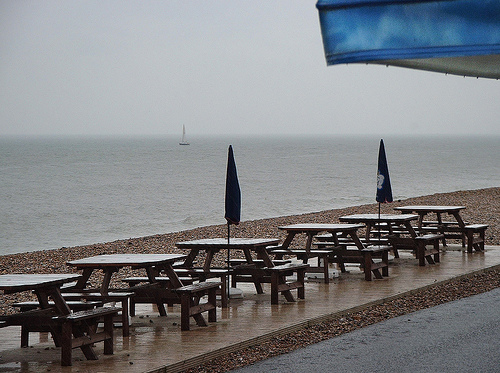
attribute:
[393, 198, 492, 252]
picnic table — wooden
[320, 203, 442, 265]
picnic table — wooden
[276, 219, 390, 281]
picnic table — wooden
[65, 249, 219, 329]
picnic table — wooden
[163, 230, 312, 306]
picnic table — wooden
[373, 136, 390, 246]
umbrella — blue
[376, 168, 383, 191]
logo — white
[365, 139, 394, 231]
canopy — blue, white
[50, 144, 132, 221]
water — large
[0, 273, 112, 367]
table — wooden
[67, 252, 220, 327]
table — wooden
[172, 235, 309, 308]
table — wooden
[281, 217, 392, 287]
table — wooden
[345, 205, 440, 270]
table — wooden, empty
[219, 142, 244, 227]
umbrella — closed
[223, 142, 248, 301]
umbrella — beach, closed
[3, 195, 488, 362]
tables — empty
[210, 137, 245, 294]
umbrella — CLOSED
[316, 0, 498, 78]
fabric canopy — part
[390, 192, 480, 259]
table — empty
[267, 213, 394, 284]
table — empty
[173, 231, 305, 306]
table — empty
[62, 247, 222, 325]
table — empty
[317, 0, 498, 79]
overhang — blue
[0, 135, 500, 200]
ocean — calm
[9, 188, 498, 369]
surface — wet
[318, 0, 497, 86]
porch roof — blue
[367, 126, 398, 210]
umbrella — blue, closed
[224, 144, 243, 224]
umbrella — white, closed